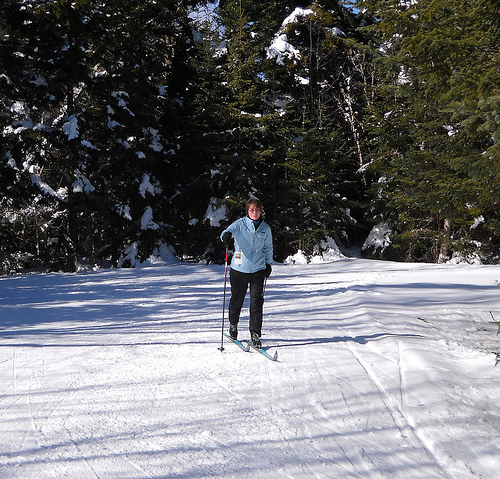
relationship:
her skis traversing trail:
[224, 327, 252, 354] [14, 277, 487, 477]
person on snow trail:
[219, 197, 273, 350] [147, 218, 457, 477]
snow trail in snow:
[141, 254, 416, 462] [326, 277, 464, 472]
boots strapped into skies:
[227, 321, 269, 347] [224, 313, 280, 363]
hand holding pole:
[220, 232, 233, 246] [216, 242, 228, 354]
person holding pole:
[219, 197, 273, 350] [215, 232, 230, 360]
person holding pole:
[219, 197, 273, 350] [259, 267, 269, 335]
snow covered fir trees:
[6, 280, 497, 475] [4, 0, 496, 265]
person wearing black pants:
[219, 197, 273, 350] [226, 263, 266, 343]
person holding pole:
[219, 197, 273, 350] [216, 242, 228, 354]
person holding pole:
[219, 197, 273, 350] [260, 264, 268, 324]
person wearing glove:
[219, 197, 273, 350] [215, 231, 234, 244]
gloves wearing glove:
[216, 223, 279, 270] [265, 261, 273, 272]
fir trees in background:
[388, 0, 500, 267] [19, 70, 483, 274]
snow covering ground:
[6, 280, 497, 475] [9, 267, 494, 474]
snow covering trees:
[69, 86, 178, 265] [54, 51, 454, 261]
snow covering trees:
[228, 13, 309, 123] [54, 51, 454, 261]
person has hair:
[219, 197, 273, 350] [245, 201, 265, 219]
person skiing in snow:
[219, 197, 273, 350] [6, 280, 497, 475]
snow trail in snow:
[141, 254, 416, 462] [9, 338, 476, 472]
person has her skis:
[219, 197, 273, 350] [188, 312, 311, 344]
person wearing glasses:
[219, 197, 273, 350] [246, 207, 261, 215]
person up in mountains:
[219, 197, 273, 350] [6, 4, 484, 469]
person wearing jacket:
[219, 197, 273, 350] [218, 215, 273, 274]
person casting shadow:
[190, 183, 359, 394] [268, 333, 381, 349]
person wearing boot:
[219, 197, 273, 350] [228, 321, 238, 341]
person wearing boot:
[219, 197, 273, 350] [248, 332, 261, 349]